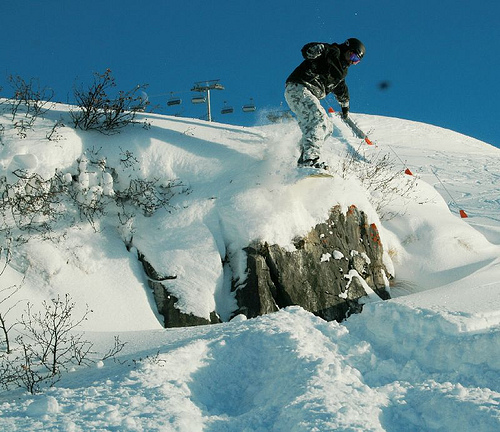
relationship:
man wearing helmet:
[277, 37, 380, 170] [340, 38, 364, 65]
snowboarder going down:
[277, 37, 380, 170] [280, 128, 409, 224]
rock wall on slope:
[128, 206, 399, 326] [7, 136, 500, 431]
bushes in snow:
[6, 72, 176, 391] [7, 136, 500, 431]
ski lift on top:
[157, 78, 262, 122] [4, 3, 499, 133]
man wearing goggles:
[277, 37, 380, 170] [346, 50, 360, 66]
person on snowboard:
[277, 37, 380, 170] [296, 157, 327, 179]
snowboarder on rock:
[277, 37, 380, 170] [128, 206, 399, 326]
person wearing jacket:
[277, 37, 380, 170] [283, 40, 357, 102]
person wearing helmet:
[277, 37, 380, 170] [340, 38, 364, 65]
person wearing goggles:
[277, 37, 380, 170] [346, 50, 360, 66]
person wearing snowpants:
[277, 37, 380, 170] [281, 80, 339, 172]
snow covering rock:
[7, 136, 500, 431] [128, 206, 399, 326]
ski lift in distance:
[157, 78, 262, 122] [1, 63, 500, 129]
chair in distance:
[193, 87, 206, 106] [1, 63, 500, 129]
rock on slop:
[128, 206, 399, 326] [108, 122, 495, 365]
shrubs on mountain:
[6, 72, 176, 391] [7, 136, 500, 431]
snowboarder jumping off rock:
[277, 37, 380, 170] [128, 206, 399, 326]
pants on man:
[281, 80, 339, 172] [277, 37, 380, 170]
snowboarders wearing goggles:
[277, 37, 380, 170] [346, 50, 360, 66]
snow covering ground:
[7, 136, 500, 431] [6, 108, 481, 415]